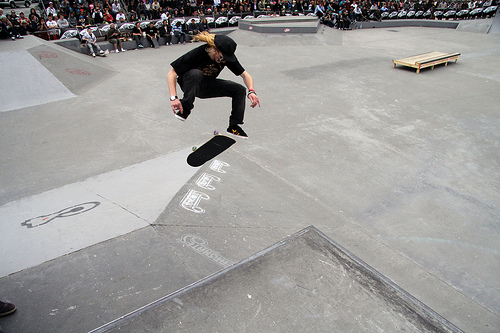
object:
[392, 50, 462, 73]
wood object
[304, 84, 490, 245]
concrete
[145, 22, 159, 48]
person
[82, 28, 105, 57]
spectator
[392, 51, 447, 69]
platform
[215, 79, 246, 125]
leg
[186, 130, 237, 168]
black skateboard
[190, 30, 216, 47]
hair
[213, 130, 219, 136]
wheels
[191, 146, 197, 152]
wheels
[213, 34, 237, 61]
cap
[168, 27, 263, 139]
girl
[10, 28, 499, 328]
floor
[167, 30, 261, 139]
man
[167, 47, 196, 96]
arm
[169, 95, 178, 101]
watch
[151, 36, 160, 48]
skateboard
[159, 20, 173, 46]
peron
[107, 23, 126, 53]
person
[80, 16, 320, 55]
bench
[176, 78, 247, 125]
black pants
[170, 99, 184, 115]
hand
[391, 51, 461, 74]
rail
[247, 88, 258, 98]
bracelets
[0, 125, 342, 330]
ground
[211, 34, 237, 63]
man's head